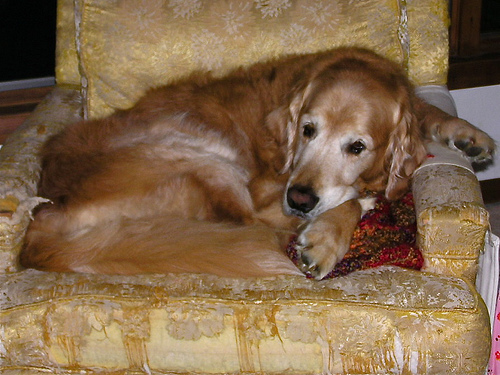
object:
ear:
[253, 85, 306, 182]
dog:
[12, 44, 497, 281]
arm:
[413, 99, 460, 141]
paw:
[440, 129, 498, 174]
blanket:
[280, 189, 425, 285]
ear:
[380, 106, 430, 202]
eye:
[338, 137, 368, 157]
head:
[262, 58, 430, 221]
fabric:
[151, 12, 187, 33]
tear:
[389, 332, 407, 374]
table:
[0, 81, 56, 148]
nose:
[284, 182, 321, 213]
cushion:
[0, 265, 489, 374]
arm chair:
[3, 0, 491, 374]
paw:
[285, 227, 337, 281]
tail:
[20, 210, 306, 280]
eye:
[298, 120, 317, 140]